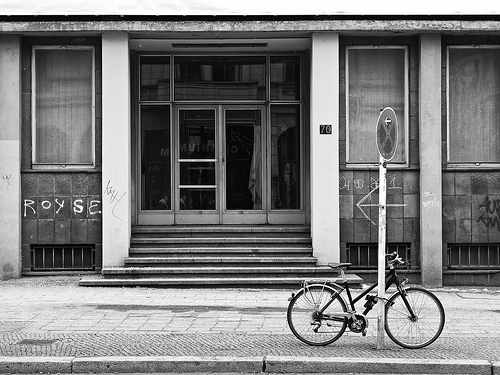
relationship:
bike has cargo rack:
[286, 249, 447, 352] [297, 273, 342, 288]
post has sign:
[376, 164, 389, 352] [373, 106, 399, 169]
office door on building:
[219, 105, 268, 227] [0, 21, 498, 290]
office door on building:
[174, 102, 223, 230] [0, 21, 498, 290]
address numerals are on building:
[316, 122, 335, 137] [0, 21, 498, 290]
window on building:
[28, 44, 97, 173] [0, 21, 498, 290]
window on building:
[343, 44, 410, 169] [0, 21, 498, 290]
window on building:
[443, 42, 499, 173] [0, 21, 498, 290]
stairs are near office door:
[78, 224, 363, 287] [219, 105, 268, 227]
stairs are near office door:
[78, 224, 363, 287] [174, 102, 223, 230]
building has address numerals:
[0, 21, 498, 290] [316, 122, 335, 137]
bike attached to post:
[286, 249, 447, 352] [376, 164, 389, 352]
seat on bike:
[329, 260, 353, 270] [286, 249, 447, 352]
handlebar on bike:
[381, 251, 397, 261] [286, 249, 447, 352]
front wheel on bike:
[385, 286, 447, 352] [286, 249, 447, 352]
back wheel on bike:
[285, 282, 349, 349] [286, 249, 447, 352]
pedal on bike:
[347, 310, 358, 328] [286, 249, 447, 352]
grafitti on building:
[23, 196, 105, 222] [0, 21, 498, 290]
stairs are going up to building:
[78, 224, 363, 287] [0, 21, 498, 290]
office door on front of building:
[219, 105, 268, 227] [0, 21, 498, 290]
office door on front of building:
[174, 102, 223, 230] [0, 21, 498, 290]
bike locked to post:
[286, 249, 447, 352] [376, 164, 389, 352]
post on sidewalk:
[376, 164, 389, 352] [3, 284, 499, 367]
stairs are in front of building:
[78, 224, 363, 287] [0, 21, 498, 290]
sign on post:
[373, 106, 399, 169] [376, 164, 389, 352]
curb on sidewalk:
[2, 350, 494, 374] [3, 284, 499, 367]